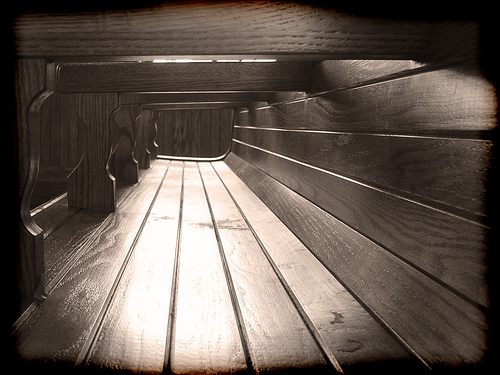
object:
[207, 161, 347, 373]
crack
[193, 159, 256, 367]
crack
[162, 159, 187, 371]
crack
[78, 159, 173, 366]
crack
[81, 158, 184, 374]
plank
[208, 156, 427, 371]
planks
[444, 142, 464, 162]
ground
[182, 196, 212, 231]
grain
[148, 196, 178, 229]
grain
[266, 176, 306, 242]
grain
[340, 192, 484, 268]
grain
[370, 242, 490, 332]
grain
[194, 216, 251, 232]
carvings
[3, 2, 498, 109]
seat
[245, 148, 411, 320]
wood grain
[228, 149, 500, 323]
crevice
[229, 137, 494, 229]
crevice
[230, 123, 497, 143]
crevice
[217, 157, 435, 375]
crevice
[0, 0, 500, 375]
wood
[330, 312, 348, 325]
mark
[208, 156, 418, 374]
planks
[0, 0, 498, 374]
bench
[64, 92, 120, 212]
plank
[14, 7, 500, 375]
seat divider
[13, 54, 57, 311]
plank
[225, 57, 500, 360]
backsit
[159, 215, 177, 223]
mark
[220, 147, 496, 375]
planks